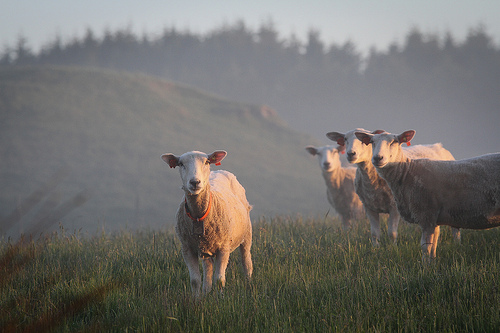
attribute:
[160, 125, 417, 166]
ears — pointy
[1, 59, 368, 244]
hill — grassy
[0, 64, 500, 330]
grass — tall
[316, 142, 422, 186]
noses — black, small, round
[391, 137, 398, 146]
eyes — slanted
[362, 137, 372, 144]
eyes — slanted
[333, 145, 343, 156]
eyes — slanted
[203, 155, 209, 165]
eyes — slanted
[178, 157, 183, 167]
eyes — slanted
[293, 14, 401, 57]
sky — grayish blue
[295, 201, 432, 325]
field — grassy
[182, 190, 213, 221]
collar — orange